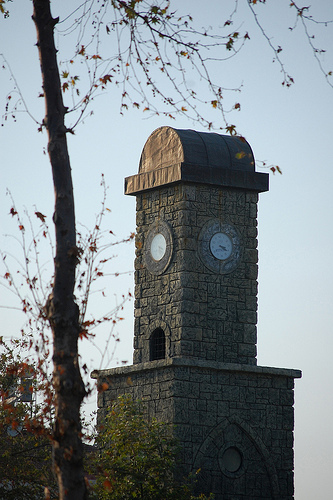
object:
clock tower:
[89, 124, 301, 498]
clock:
[207, 230, 232, 260]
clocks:
[149, 233, 167, 261]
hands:
[215, 239, 228, 253]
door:
[145, 320, 170, 361]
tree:
[30, 0, 89, 499]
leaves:
[75, 45, 122, 96]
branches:
[53, 0, 249, 137]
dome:
[123, 125, 268, 195]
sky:
[11, 11, 31, 56]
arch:
[187, 413, 280, 498]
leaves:
[81, 393, 215, 499]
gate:
[220, 469, 246, 499]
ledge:
[90, 356, 302, 378]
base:
[90, 354, 303, 499]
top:
[124, 125, 268, 366]